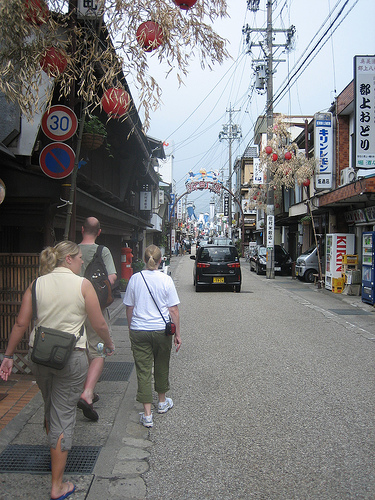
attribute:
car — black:
[187, 236, 248, 297]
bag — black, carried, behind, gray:
[25, 269, 87, 370]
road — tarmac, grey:
[170, 286, 374, 499]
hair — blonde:
[30, 235, 93, 279]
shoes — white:
[137, 395, 182, 432]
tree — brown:
[5, 0, 221, 145]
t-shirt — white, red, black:
[121, 267, 182, 334]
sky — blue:
[148, 70, 243, 132]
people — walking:
[0, 209, 186, 500]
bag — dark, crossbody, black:
[82, 243, 118, 310]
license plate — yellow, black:
[210, 272, 232, 287]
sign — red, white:
[42, 101, 83, 144]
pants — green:
[123, 326, 179, 403]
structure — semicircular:
[162, 174, 250, 247]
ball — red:
[90, 79, 137, 129]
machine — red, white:
[319, 224, 356, 294]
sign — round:
[35, 137, 82, 184]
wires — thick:
[242, 1, 356, 104]